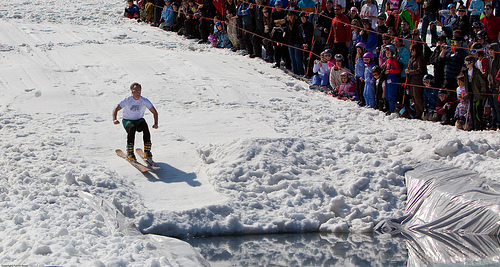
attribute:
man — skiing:
[112, 80, 164, 153]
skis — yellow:
[114, 143, 168, 174]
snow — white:
[4, 77, 500, 265]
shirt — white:
[117, 94, 152, 123]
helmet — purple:
[362, 50, 373, 61]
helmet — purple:
[355, 41, 367, 50]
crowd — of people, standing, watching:
[128, 1, 497, 124]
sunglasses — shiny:
[133, 89, 142, 93]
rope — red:
[325, 16, 329, 18]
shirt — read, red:
[324, 15, 350, 46]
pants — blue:
[386, 72, 399, 117]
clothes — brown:
[413, 57, 421, 118]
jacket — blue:
[359, 29, 378, 55]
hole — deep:
[147, 225, 498, 266]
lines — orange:
[305, 0, 318, 80]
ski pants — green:
[122, 117, 156, 161]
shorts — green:
[121, 119, 151, 132]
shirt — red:
[385, 56, 403, 79]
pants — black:
[243, 25, 258, 53]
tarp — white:
[407, 158, 500, 235]